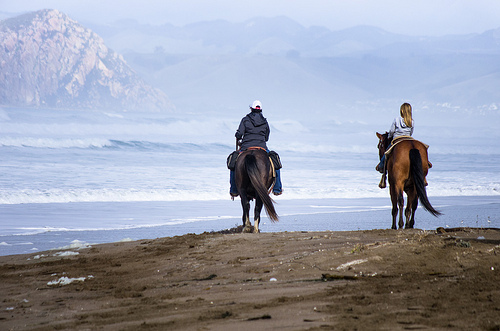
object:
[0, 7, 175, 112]
hill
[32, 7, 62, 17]
tip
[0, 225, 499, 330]
shore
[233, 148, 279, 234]
horse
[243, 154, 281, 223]
tail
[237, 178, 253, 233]
back leg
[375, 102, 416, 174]
girl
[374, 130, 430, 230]
horse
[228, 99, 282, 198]
man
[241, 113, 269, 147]
back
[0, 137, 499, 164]
wave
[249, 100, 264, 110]
cap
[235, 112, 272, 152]
winter jacket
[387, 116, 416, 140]
hoody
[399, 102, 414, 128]
hair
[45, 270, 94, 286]
patch of snow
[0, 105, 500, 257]
water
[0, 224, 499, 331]
dirt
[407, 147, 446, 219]
tail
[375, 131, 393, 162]
head